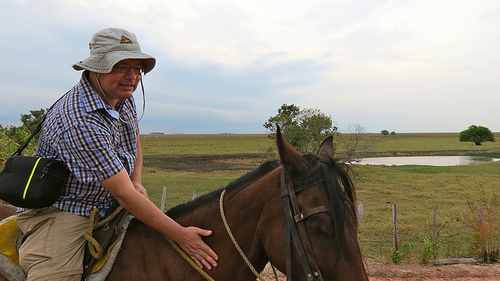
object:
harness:
[285, 147, 356, 280]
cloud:
[146, 10, 259, 48]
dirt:
[385, 255, 422, 279]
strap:
[138, 79, 145, 122]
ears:
[313, 133, 337, 169]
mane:
[139, 162, 281, 225]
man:
[16, 27, 221, 280]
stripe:
[21, 158, 44, 200]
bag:
[0, 86, 71, 209]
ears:
[273, 123, 312, 177]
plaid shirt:
[16, 71, 139, 218]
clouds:
[319, 17, 462, 78]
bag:
[1, 86, 76, 209]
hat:
[70, 26, 161, 76]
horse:
[1, 122, 373, 280]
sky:
[3, 2, 496, 134]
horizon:
[2, 129, 499, 136]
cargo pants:
[13, 205, 103, 280]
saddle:
[0, 200, 133, 279]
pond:
[338, 148, 499, 171]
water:
[402, 154, 468, 163]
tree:
[457, 122, 494, 149]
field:
[1, 131, 499, 280]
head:
[85, 44, 146, 100]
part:
[229, 47, 260, 83]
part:
[426, 172, 456, 203]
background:
[0, 1, 499, 160]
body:
[2, 76, 220, 280]